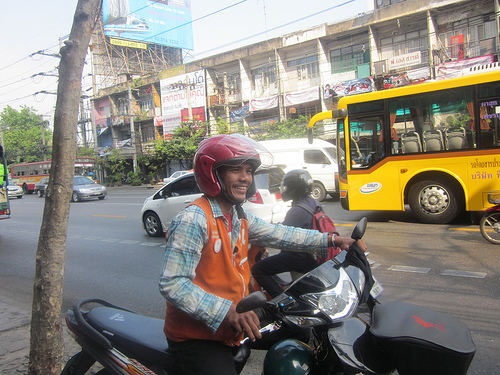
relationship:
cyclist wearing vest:
[157, 132, 367, 374] [185, 188, 255, 346]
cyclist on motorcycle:
[157, 132, 367, 374] [55, 213, 477, 374]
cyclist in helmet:
[157, 132, 367, 374] [191, 132, 273, 205]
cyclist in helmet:
[157, 132, 367, 374] [188, 131, 260, 198]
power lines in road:
[102, 15, 248, 72] [59, 167, 426, 299]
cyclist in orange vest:
[157, 132, 367, 374] [163, 197, 253, 345]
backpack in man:
[310, 205, 342, 260] [251, 169, 342, 299]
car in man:
[140, 164, 293, 237] [251, 169, 342, 299]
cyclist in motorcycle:
[157, 132, 367, 374] [55, 216, 476, 375]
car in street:
[140, 168, 291, 237] [0, 183, 499, 373]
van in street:
[236, 137, 346, 197] [8, 182, 496, 344]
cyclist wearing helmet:
[157, 132, 367, 374] [184, 131, 264, 190]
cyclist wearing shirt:
[157, 132, 367, 374] [143, 190, 253, 342]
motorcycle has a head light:
[55, 216, 476, 375] [278, 267, 365, 327]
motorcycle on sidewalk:
[55, 213, 477, 374] [1, 308, 127, 373]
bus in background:
[315, 72, 497, 239] [302, 56, 485, 226]